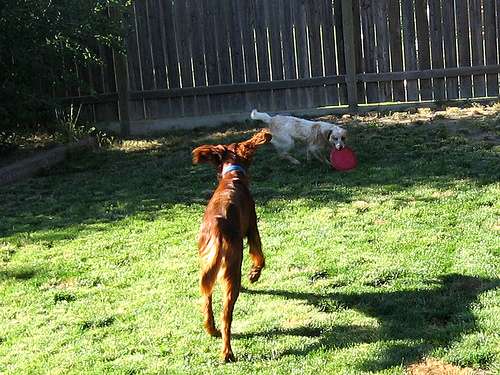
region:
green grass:
[88, 272, 140, 352]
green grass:
[97, 286, 160, 346]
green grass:
[61, 305, 162, 365]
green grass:
[100, 327, 151, 357]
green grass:
[11, 276, 166, 362]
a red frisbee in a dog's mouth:
[325, 144, 365, 173]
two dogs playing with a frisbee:
[184, 98, 368, 366]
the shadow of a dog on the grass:
[242, 265, 493, 374]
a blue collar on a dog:
[217, 155, 249, 180]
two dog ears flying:
[180, 122, 280, 164]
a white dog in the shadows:
[247, 102, 349, 166]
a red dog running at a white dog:
[188, 113, 278, 372]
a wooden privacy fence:
[49, 3, 496, 135]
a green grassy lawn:
[0, 109, 497, 372]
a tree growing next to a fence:
[0, 1, 130, 152]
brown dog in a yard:
[162, 121, 292, 366]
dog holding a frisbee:
[243, 90, 368, 175]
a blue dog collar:
[215, 161, 252, 185]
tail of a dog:
[195, 213, 232, 300]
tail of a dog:
[242, 101, 282, 128]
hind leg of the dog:
[208, 245, 255, 367]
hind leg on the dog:
[195, 276, 225, 343]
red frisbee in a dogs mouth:
[326, 141, 361, 173]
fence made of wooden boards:
[0, 0, 497, 144]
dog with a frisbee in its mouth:
[240, 102, 365, 174]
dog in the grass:
[185, 136, 270, 274]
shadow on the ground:
[351, 252, 482, 373]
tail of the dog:
[178, 233, 240, 298]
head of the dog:
[182, 126, 272, 190]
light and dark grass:
[383, 166, 449, 233]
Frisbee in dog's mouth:
[304, 139, 366, 181]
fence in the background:
[173, 28, 289, 74]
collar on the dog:
[216, 150, 258, 183]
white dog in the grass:
[275, 118, 347, 148]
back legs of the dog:
[185, 291, 254, 332]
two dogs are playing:
[165, 65, 377, 266]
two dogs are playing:
[171, 95, 285, 283]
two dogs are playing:
[122, 40, 340, 344]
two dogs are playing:
[190, 123, 370, 369]